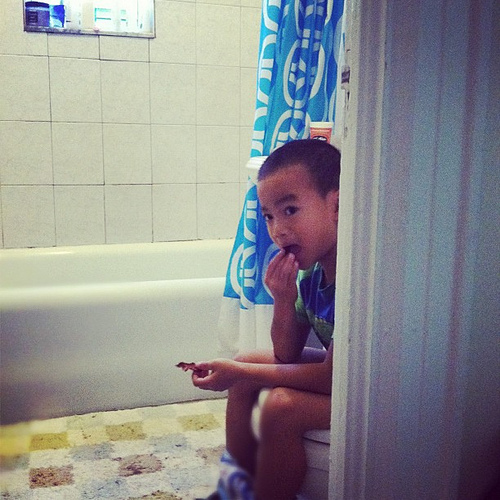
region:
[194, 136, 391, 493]
young boy sitting on toilet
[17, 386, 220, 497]
checkered rug on floor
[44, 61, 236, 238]
white tiled bathroom wall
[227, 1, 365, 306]
blue and white shower curtain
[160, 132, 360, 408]
young boy eating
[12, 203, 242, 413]
white bath tub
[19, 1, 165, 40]
window ledge with bath items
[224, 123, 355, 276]
young boy with black hair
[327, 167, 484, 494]
white bathroom door frame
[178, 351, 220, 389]
food in young boys hand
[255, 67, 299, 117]
part of a curtain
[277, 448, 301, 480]
part of the left leg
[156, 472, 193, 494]
part of the floor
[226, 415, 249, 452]
part of the right leg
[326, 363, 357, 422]
edge of a door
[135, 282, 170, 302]
edge of a bathtab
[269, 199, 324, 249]
face of a boy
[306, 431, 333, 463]
edge of a toilet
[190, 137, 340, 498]
boy sitting on toilet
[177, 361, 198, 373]
a snack the boy is eating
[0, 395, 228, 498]
brightly-colored bathroom floor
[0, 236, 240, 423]
a white bathtub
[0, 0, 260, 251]
white tiles above the bathtub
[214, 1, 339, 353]
a blue and white shower curtain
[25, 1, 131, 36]
personal care products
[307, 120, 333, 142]
a cup on the sink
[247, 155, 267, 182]
a white sink behind the boy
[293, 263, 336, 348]
a green and blue t-shirt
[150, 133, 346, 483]
boy sitting on toilet and eating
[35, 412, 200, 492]
colored checkerboard squares on bathmat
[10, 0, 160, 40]
containers on window sill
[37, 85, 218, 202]
white tiles against wall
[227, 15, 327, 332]
blue shower curtain with white circles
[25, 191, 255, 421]
white tub against wall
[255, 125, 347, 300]
boy leaning forward to look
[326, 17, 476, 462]
door jamb and wall on boy's side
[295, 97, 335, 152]
tube behind boy's head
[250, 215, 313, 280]
fingers near open mouth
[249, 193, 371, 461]
child sitting on toilet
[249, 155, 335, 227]
kid has short dark hair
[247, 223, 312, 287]
Kid eating while going to the bathroom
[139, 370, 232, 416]
Piece of bacon in boy's hand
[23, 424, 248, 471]
Checkered bath mat on floor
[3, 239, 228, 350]
white bathtub in bathroom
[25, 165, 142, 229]
white tiles on the wall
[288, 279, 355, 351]
Boy wearing blue shirt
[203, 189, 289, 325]
Blue and white shower curtain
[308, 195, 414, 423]
white door way into bathroom